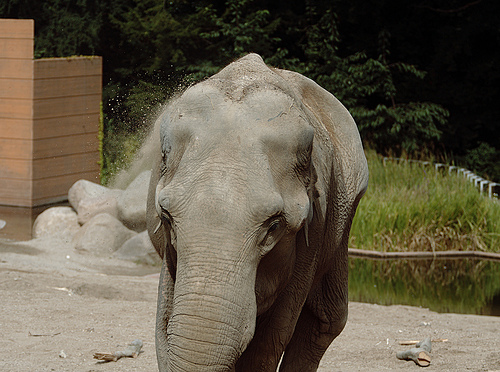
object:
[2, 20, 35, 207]
wall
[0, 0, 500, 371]
scene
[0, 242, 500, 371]
dirt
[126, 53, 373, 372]
elephant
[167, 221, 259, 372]
trunk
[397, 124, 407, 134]
leaves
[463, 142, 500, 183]
tree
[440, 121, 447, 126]
leaves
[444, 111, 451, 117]
leaves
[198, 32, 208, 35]
leaves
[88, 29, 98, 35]
leaves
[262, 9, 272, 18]
leaves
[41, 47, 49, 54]
leaves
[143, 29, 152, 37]
leaves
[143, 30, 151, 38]
leaves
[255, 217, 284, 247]
eye